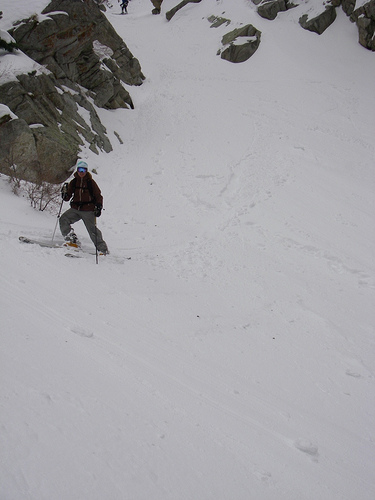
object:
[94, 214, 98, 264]
ski poles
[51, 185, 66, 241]
ski poles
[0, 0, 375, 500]
ski slope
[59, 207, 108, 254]
pants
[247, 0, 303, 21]
rock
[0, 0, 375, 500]
snow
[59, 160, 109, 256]
man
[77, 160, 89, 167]
hat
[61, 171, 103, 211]
jacket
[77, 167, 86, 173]
ski goggles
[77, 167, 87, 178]
face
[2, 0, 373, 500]
ground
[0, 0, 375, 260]
hill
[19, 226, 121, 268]
skiis